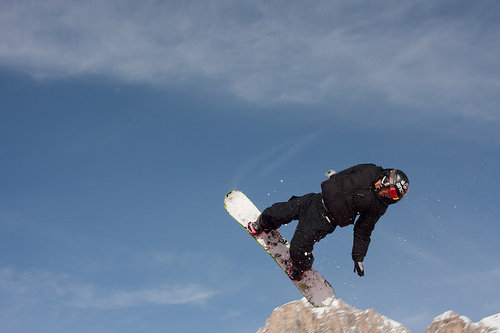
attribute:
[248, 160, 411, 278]
man — leaning, jumping, snowboarding, performing, flying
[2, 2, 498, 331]
sky — blue, light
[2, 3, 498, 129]
cloud — white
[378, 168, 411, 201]
helmet — black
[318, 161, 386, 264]
jacket — black, down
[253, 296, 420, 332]
mountain — rocky, snowy, background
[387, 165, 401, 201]
goggles — yellow, red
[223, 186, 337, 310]
snowboard — white, attached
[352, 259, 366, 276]
glove — reaching, black, out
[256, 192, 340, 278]
pants — black